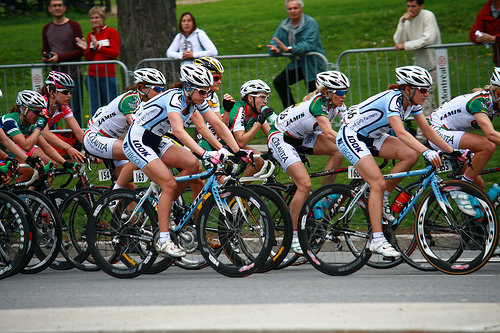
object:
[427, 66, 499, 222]
cyclist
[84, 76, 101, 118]
leg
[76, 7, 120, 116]
person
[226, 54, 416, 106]
gate